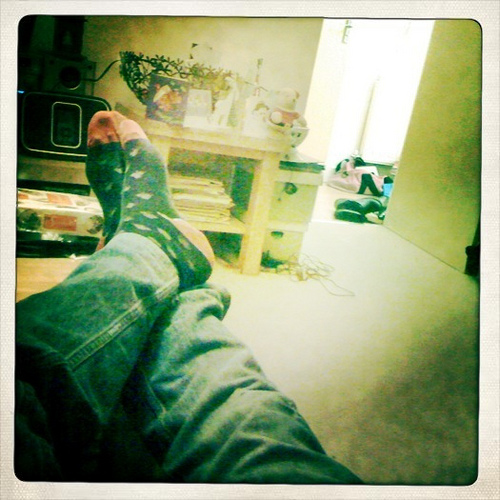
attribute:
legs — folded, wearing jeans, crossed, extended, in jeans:
[22, 109, 367, 482]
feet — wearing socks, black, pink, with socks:
[108, 109, 217, 286]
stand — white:
[16, 103, 284, 274]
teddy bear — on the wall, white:
[268, 81, 308, 130]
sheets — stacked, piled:
[167, 165, 235, 225]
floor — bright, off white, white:
[20, 180, 479, 485]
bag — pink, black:
[327, 151, 384, 200]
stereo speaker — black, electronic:
[20, 85, 112, 163]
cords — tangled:
[260, 253, 353, 301]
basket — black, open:
[118, 45, 241, 124]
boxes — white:
[234, 162, 324, 224]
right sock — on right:
[82, 110, 122, 256]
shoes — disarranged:
[334, 193, 387, 225]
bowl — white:
[261, 115, 309, 153]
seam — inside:
[27, 278, 180, 410]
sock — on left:
[117, 109, 214, 289]